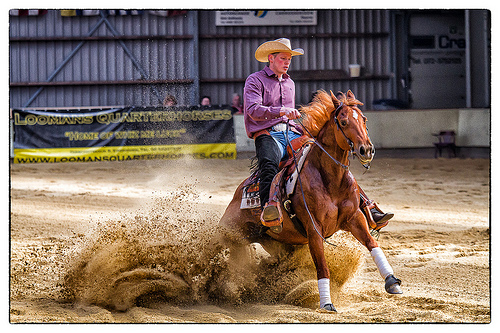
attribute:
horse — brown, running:
[213, 89, 405, 315]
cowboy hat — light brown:
[254, 38, 305, 63]